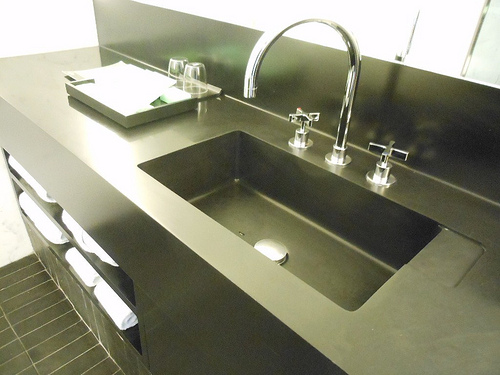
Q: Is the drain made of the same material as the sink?
A: Yes, both the drain and the sink are made of metal.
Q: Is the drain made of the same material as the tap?
A: Yes, both the drain and the tap are made of metal.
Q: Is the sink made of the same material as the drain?
A: Yes, both the sink and the drain are made of metal.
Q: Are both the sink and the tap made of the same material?
A: Yes, both the sink and the tap are made of metal.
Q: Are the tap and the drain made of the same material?
A: Yes, both the tap and the drain are made of metal.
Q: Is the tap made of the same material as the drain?
A: Yes, both the tap and the drain are made of metal.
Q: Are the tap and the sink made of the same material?
A: Yes, both the tap and the sink are made of metal.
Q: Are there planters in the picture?
A: No, there are no planters.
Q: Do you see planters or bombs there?
A: No, there are no planters or bombs.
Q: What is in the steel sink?
A: The drain is in the sink.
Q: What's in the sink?
A: The drain is in the sink.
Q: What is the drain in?
A: The drain is in the sink.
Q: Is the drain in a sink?
A: Yes, the drain is in a sink.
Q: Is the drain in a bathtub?
A: No, the drain is in a sink.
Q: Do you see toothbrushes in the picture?
A: No, there are no toothbrushes.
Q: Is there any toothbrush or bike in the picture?
A: No, there are no toothbrushes or bikes.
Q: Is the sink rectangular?
A: Yes, the sink is rectangular.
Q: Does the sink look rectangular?
A: Yes, the sink is rectangular.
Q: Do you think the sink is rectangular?
A: Yes, the sink is rectangular.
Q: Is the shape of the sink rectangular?
A: Yes, the sink is rectangular.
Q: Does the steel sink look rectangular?
A: Yes, the sink is rectangular.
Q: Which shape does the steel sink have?
A: The sink has rectangular shape.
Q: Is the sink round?
A: No, the sink is rectangular.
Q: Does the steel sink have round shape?
A: No, the sink is rectangular.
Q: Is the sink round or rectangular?
A: The sink is rectangular.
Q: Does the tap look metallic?
A: Yes, the tap is metallic.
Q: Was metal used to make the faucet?
A: Yes, the faucet is made of metal.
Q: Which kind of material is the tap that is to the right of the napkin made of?
A: The faucet is made of metal.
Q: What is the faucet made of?
A: The faucet is made of metal.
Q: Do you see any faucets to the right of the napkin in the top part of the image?
A: Yes, there is a faucet to the right of the napkin.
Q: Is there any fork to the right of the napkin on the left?
A: No, there is a faucet to the right of the napkin.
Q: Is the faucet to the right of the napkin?
A: Yes, the faucet is to the right of the napkin.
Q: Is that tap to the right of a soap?
A: No, the tap is to the right of the napkin.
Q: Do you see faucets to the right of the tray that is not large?
A: Yes, there is a faucet to the right of the tray.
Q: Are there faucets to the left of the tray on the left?
A: No, the faucet is to the right of the tray.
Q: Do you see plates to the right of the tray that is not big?
A: No, there is a faucet to the right of the tray.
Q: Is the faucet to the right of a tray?
A: Yes, the faucet is to the right of a tray.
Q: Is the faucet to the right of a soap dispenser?
A: No, the faucet is to the right of a tray.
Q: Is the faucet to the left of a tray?
A: No, the faucet is to the right of a tray.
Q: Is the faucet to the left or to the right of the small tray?
A: The faucet is to the right of the tray.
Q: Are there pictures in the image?
A: No, there are no pictures.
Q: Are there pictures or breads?
A: No, there are no pictures or breads.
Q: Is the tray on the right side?
A: No, the tray is on the left of the image.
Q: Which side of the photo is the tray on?
A: The tray is on the left of the image.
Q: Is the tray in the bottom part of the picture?
A: No, the tray is in the top of the image.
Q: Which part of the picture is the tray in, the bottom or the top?
A: The tray is in the top of the image.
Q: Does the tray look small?
A: Yes, the tray is small.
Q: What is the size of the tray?
A: The tray is small.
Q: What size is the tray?
A: The tray is small.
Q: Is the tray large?
A: No, the tray is small.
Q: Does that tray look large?
A: No, the tray is small.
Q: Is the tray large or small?
A: The tray is small.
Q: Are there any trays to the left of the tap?
A: Yes, there is a tray to the left of the tap.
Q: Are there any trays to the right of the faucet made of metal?
A: No, the tray is to the left of the faucet.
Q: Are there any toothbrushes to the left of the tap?
A: No, there is a tray to the left of the tap.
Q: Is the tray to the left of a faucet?
A: Yes, the tray is to the left of a faucet.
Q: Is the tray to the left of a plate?
A: No, the tray is to the left of a faucet.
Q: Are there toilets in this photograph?
A: No, there are no toilets.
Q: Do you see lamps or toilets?
A: No, there are no toilets or lamps.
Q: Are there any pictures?
A: No, there are no pictures.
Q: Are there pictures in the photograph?
A: No, there are no pictures.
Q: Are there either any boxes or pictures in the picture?
A: No, there are no pictures or boxes.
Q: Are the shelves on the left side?
A: Yes, the shelves are on the left of the image.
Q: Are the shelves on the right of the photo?
A: No, the shelves are on the left of the image.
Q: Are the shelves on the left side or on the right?
A: The shelves are on the left of the image.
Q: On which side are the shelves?
A: The shelves are on the left of the image.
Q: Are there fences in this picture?
A: No, there are no fences.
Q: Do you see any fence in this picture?
A: No, there are no fences.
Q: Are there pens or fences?
A: No, there are no fences or pens.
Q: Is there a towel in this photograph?
A: Yes, there is a towel.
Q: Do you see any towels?
A: Yes, there is a towel.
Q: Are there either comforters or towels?
A: Yes, there is a towel.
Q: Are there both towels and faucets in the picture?
A: Yes, there are both a towel and a faucet.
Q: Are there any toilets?
A: No, there are no toilets.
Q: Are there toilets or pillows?
A: No, there are no toilets or pillows.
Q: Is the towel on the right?
A: No, the towel is on the left of the image.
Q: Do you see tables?
A: Yes, there is a table.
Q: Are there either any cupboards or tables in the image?
A: Yes, there is a table.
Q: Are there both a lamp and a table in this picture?
A: No, there is a table but no lamps.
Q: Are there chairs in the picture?
A: No, there are no chairs.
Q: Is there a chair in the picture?
A: No, there are no chairs.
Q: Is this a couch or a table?
A: This is a table.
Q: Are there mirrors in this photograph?
A: Yes, there is a mirror.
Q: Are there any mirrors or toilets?
A: Yes, there is a mirror.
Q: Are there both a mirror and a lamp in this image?
A: No, there is a mirror but no lamps.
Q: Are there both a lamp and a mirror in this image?
A: No, there is a mirror but no lamps.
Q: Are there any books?
A: No, there are no books.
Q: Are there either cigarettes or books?
A: No, there are no books or cigarettes.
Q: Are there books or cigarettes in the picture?
A: No, there are no books or cigarettes.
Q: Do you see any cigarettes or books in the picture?
A: No, there are no books or cigarettes.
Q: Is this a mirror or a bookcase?
A: This is a mirror.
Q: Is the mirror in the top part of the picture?
A: Yes, the mirror is in the top of the image.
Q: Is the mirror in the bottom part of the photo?
A: No, the mirror is in the top of the image.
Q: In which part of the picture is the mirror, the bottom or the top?
A: The mirror is in the top of the image.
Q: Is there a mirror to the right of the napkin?
A: Yes, there is a mirror to the right of the napkin.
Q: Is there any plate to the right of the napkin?
A: No, there is a mirror to the right of the napkin.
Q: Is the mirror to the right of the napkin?
A: Yes, the mirror is to the right of the napkin.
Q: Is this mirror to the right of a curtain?
A: No, the mirror is to the right of the napkin.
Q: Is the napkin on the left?
A: Yes, the napkin is on the left of the image.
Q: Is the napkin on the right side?
A: No, the napkin is on the left of the image.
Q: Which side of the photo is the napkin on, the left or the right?
A: The napkin is on the left of the image.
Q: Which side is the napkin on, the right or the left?
A: The napkin is on the left of the image.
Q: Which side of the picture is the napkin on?
A: The napkin is on the left of the image.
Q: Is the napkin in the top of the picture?
A: Yes, the napkin is in the top of the image.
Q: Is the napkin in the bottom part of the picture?
A: No, the napkin is in the top of the image.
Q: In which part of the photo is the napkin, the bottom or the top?
A: The napkin is in the top of the image.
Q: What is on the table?
A: The napkin is on the table.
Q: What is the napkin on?
A: The napkin is on the table.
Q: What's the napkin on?
A: The napkin is on the table.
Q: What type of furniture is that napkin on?
A: The napkin is on the table.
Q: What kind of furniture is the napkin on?
A: The napkin is on the table.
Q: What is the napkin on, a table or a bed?
A: The napkin is on a table.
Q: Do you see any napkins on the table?
A: Yes, there is a napkin on the table.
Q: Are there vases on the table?
A: No, there is a napkin on the table.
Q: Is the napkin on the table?
A: Yes, the napkin is on the table.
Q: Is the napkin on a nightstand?
A: No, the napkin is on the table.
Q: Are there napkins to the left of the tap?
A: Yes, there is a napkin to the left of the tap.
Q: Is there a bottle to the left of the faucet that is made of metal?
A: No, there is a napkin to the left of the tap.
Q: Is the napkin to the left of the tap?
A: Yes, the napkin is to the left of the tap.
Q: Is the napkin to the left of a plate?
A: No, the napkin is to the left of the tap.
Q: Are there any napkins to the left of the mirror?
A: Yes, there is a napkin to the left of the mirror.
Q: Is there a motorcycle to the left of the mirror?
A: No, there is a napkin to the left of the mirror.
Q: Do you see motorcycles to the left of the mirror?
A: No, there is a napkin to the left of the mirror.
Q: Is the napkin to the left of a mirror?
A: Yes, the napkin is to the left of a mirror.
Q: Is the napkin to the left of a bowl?
A: No, the napkin is to the left of a mirror.